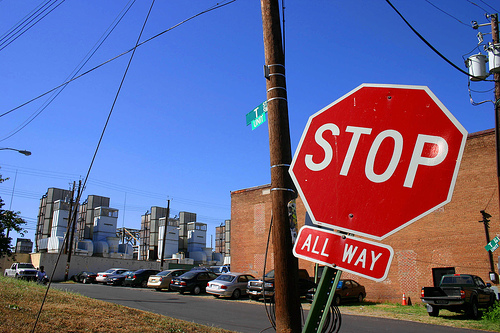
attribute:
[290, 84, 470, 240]
sign — white, red, tipped, leaning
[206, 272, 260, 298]
car — parked, silver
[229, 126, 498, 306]
building — large, brick, tall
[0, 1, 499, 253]
sky — deep blue, blue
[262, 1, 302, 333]
post — wooden, brown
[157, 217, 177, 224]
container — large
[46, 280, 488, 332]
road — cement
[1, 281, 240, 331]
grass — brown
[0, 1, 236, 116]
telephone wires — telephone wires, numerous, connected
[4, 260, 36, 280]
truck — parked, black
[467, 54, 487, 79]
electric transformer — mounted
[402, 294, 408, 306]
traffic cone — orange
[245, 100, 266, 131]
sign — green